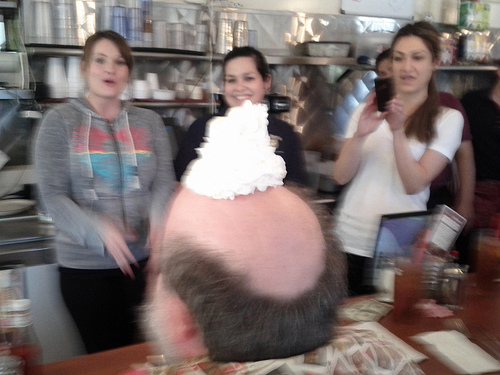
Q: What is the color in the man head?
A: White.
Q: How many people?
A: 5.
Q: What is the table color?
A: Brown.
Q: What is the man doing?
A: Sitting.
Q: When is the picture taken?
A: Daytime.